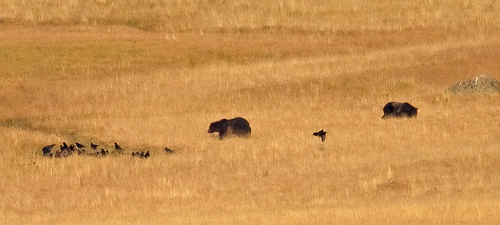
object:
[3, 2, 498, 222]
ground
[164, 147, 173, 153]
bird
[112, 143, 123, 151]
bird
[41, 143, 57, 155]
bird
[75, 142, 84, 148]
bird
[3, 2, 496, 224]
grass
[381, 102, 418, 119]
bear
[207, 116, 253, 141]
bear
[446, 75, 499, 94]
pile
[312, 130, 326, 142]
bird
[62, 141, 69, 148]
bird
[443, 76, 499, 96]
rock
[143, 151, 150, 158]
bird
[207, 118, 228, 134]
bear's head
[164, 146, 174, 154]
birds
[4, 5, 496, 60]
field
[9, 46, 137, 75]
greener grass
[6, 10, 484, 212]
pasture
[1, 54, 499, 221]
field